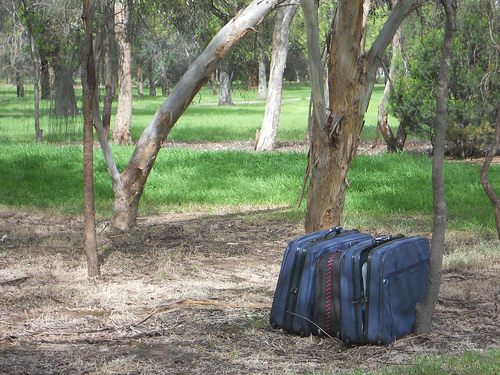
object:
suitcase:
[269, 222, 432, 345]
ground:
[0, 214, 499, 373]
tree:
[293, 1, 425, 237]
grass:
[0, 75, 499, 230]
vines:
[368, 36, 431, 156]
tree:
[393, 1, 465, 337]